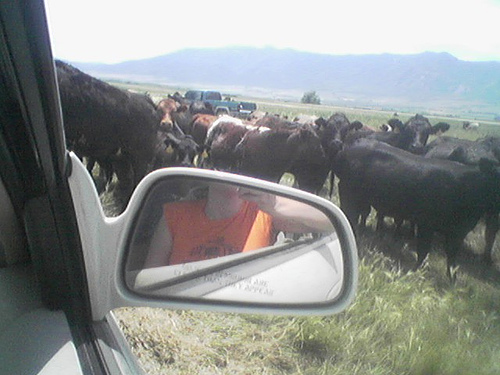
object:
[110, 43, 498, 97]
mountain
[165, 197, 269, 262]
shirt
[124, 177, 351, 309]
mirror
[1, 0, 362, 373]
truck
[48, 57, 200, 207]
cattle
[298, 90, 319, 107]
bush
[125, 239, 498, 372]
grass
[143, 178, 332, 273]
person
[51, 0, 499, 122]
background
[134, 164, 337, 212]
top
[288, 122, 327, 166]
head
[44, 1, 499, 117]
sky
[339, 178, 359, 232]
leg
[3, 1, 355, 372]
car